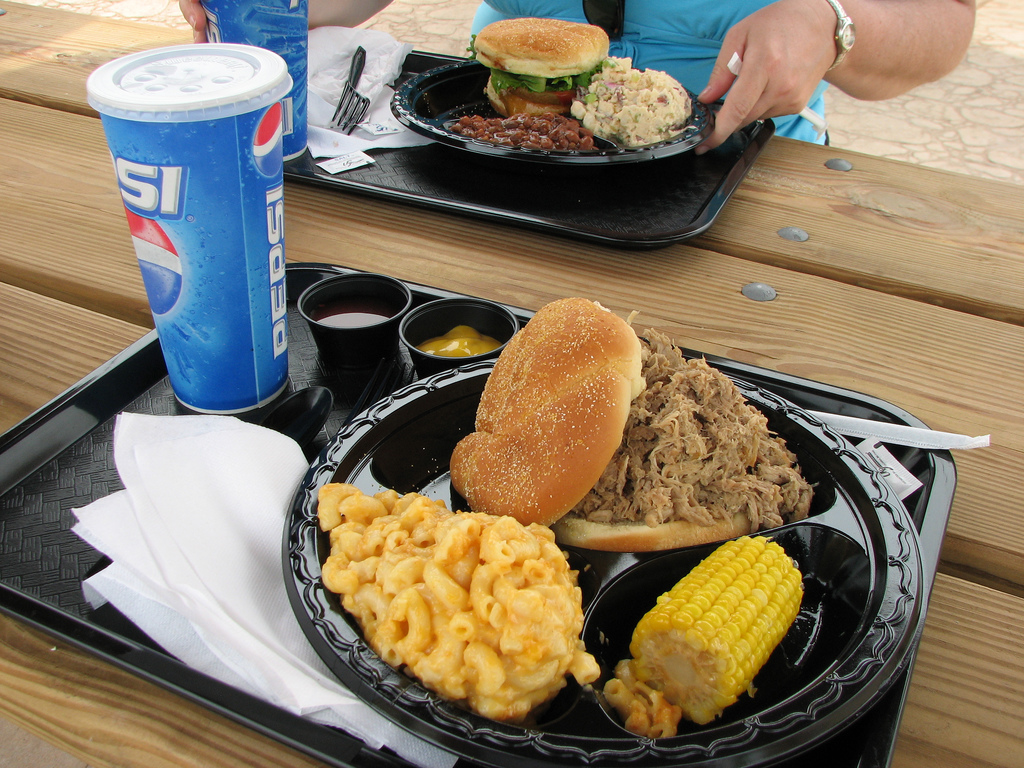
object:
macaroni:
[314, 482, 602, 723]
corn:
[629, 533, 809, 727]